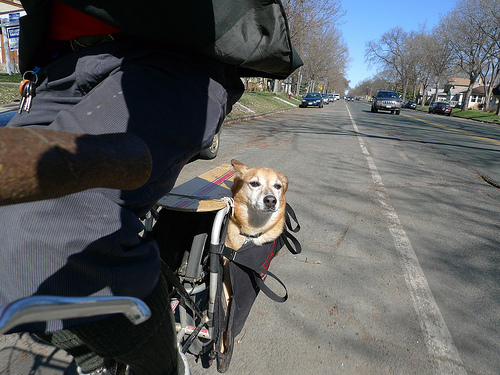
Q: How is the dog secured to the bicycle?
A: In a bag.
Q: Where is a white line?
A: On the road.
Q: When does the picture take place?
A: During the daytime.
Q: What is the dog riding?
A: A bicycle.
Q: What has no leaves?
A: The trees.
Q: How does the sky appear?
A: Blue and clear.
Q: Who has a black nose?
A: The dog.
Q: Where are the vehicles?
A: On the road.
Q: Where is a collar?
A: Around dog's neck.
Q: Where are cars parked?
A: On both sides of the road.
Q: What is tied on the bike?
A: Dog tied on a bicycle.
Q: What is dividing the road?
A: White line dividing the oad.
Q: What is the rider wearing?
A: Pair of green socks.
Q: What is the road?
A: Rough grey tarmacked road.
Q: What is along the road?
A: Bare trees along the road.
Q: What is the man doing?
A: Man riding a bicycle.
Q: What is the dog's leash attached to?
A: A bike.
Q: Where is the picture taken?
A: In the street.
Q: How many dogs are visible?
A: 1.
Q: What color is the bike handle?
A: Brown.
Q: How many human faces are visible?
A: Zero.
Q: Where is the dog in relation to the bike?
A: Behind.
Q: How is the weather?
A: Clear.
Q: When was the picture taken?
A: Daytime.